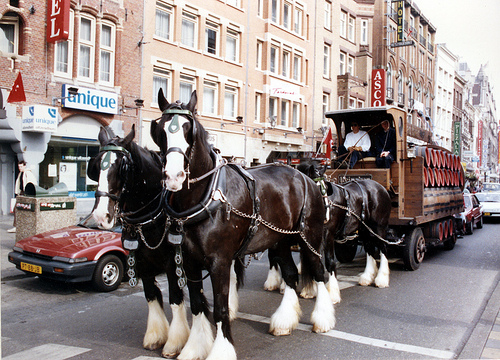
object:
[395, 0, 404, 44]
sign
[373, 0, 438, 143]
building